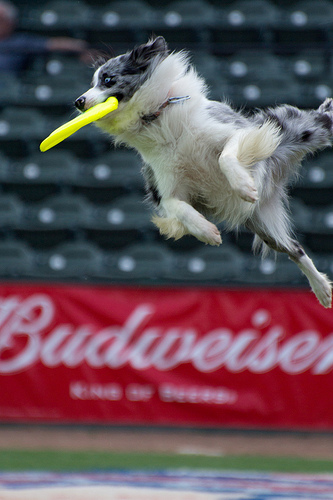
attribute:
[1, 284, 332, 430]
banner — red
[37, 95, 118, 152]
frisbee — yellow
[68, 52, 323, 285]
dog — black and white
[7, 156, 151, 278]
seats — empty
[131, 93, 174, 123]
collar — brown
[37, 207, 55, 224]
seat number — blurry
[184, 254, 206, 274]
seat number — blurry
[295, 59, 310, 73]
seat number — blurry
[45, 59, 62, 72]
seat number — blurry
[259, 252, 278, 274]
seat number — blurry